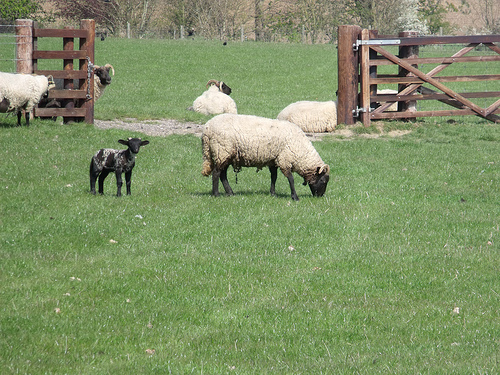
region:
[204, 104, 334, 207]
a white sheep eating grass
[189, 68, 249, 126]
a white sheep laying in grass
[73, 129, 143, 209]
a baby black sheep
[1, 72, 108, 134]
a white sheep grazing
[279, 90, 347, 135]
a white sheep laying on the ground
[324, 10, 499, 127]
a brown wooden fence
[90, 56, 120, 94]
a sheep with horns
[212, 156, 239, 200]
a white sheeps black legs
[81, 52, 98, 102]
a metal chain latch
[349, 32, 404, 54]
a metal gate hinge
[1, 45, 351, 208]
several sheep in a meadow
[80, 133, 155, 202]
this lamb looks like the black sheep of the family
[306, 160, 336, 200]
this sheep has a black face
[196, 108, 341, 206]
this is the lamb's mother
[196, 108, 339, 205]
mama sheep is grazing in the meadow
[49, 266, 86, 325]
the meadow is dotted with flowers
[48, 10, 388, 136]
this gate is open for the sheep to pass through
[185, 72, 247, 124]
a sheep lying on the ground chillin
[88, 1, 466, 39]
some of the trees in the background have no leaves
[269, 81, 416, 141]
a couple more sheep laying in the grass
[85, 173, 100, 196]
the black leg of a sheep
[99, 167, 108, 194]
the black leg of a sheep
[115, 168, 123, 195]
the black leg of a sheep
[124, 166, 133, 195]
the black leg of a sheep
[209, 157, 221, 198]
the black leg of a sheep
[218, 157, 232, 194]
the black leg of a sheep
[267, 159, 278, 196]
the black leg of a sheep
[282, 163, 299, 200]
the black leg of a sheep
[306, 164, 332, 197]
the black head of a sheep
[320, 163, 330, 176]
the ear of a sheep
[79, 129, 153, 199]
youngest sheep in the group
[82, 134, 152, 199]
black sheep in the grass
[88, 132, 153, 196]
black sheep looking toward the camera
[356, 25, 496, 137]
brown wooden gate door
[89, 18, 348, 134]
opening in the fence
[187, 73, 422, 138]
three sheep lying on the ground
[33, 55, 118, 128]
ram standing near the fence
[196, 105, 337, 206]
adult sheep closest to the camera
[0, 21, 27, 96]
wire portion of the fence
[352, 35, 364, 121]
hinges on the gate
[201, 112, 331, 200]
a white and black sheep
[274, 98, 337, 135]
a white and black sheep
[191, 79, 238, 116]
a white and black sheep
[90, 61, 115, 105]
a white and black sheep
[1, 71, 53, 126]
a white and black sheep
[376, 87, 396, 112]
a white and black sheep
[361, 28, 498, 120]
a brown fence gate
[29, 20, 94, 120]
a brown fence gate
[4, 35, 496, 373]
a green grassy pasture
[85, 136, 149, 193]
a baby black lamb